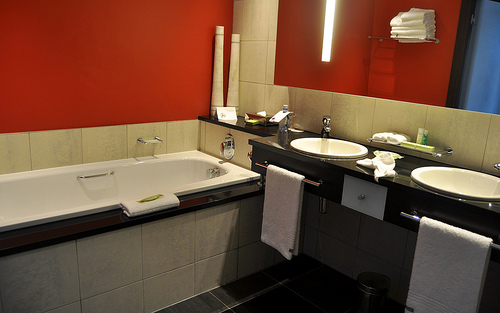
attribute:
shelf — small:
[369, 137, 451, 161]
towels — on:
[389, 7, 437, 45]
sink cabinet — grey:
[242, 125, 499, 267]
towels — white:
[254, 165, 459, 303]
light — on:
[292, 0, 361, 86]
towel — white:
[228, 157, 322, 277]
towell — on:
[257, 164, 297, 259]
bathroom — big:
[3, 7, 445, 311]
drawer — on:
[331, 165, 400, 223]